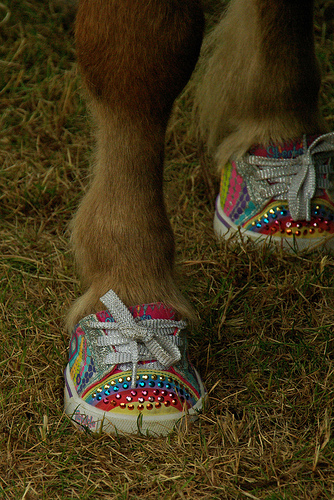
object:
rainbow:
[251, 201, 334, 235]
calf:
[66, 76, 176, 269]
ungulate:
[60, 0, 334, 438]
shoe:
[214, 131, 334, 256]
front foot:
[211, 129, 334, 264]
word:
[74, 410, 96, 435]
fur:
[71, 0, 208, 266]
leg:
[64, 0, 205, 337]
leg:
[204, 0, 321, 176]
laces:
[244, 129, 334, 221]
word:
[266, 142, 303, 160]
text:
[267, 143, 304, 160]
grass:
[0, 0, 334, 500]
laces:
[85, 288, 189, 389]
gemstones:
[92, 374, 190, 411]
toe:
[77, 370, 209, 439]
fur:
[211, 0, 322, 172]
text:
[73, 409, 96, 433]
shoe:
[63, 287, 205, 439]